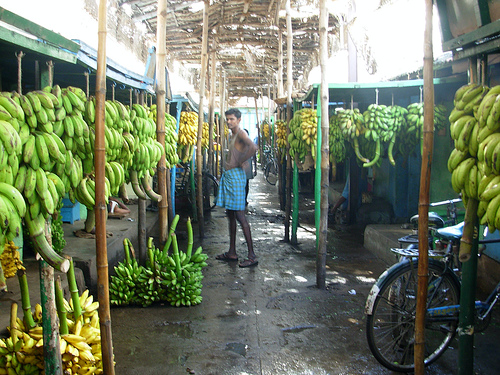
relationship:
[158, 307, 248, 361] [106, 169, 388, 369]
water on ground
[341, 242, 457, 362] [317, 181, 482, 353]
tire on bike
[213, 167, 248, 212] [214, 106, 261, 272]
shorts on man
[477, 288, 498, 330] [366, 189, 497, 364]
pedal on bicycle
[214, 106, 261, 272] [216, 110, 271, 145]
man has hair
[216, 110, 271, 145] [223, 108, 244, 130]
hair on head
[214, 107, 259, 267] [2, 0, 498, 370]
man in facility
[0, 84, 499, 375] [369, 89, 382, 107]
banana hanging from hook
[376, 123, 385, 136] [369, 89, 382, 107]
banana hanging from hook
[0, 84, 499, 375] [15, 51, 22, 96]
banana hanging from hook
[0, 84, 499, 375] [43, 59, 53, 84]
banana hanging from hook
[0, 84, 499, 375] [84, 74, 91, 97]
banana hanging from hook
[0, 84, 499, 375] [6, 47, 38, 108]
banana hanging from hook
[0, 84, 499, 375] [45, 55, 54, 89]
banana hanging from hook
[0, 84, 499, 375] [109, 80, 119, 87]
banana hanging from hook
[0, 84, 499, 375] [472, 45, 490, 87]
banana hanging from hook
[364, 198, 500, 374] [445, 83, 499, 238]
bicycle under bunch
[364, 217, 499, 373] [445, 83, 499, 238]
bicycle under bunch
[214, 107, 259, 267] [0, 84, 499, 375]
man standing beside banana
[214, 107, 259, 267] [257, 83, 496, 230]
man standing beside bananas